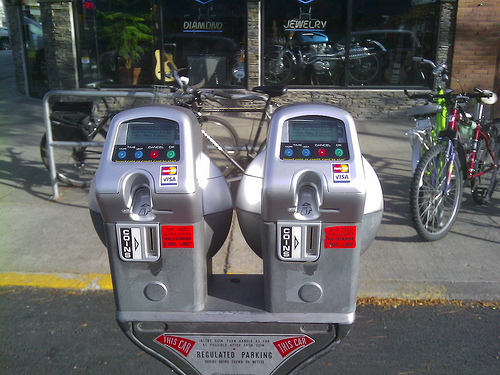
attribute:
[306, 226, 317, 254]
coin slot — pictured here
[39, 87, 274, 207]
bike rack — visible here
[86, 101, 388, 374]
parking meter — pictured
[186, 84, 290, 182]
bicycle — black, silver, parked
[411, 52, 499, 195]
bicycle — green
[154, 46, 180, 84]
guitar — beige colored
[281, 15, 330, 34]
neon sign — turned off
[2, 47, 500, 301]
sidewalk — made of cement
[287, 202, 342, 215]
credit card slot — pictured here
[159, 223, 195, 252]
sticker — red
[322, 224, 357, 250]
sign — small, red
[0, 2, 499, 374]
street scene — pictured here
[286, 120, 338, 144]
digital display — pictured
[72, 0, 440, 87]
storefront windows — pictured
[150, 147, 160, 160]
button — colored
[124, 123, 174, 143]
digital display — pictured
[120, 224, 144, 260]
sticker — white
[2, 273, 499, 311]
curb — painted